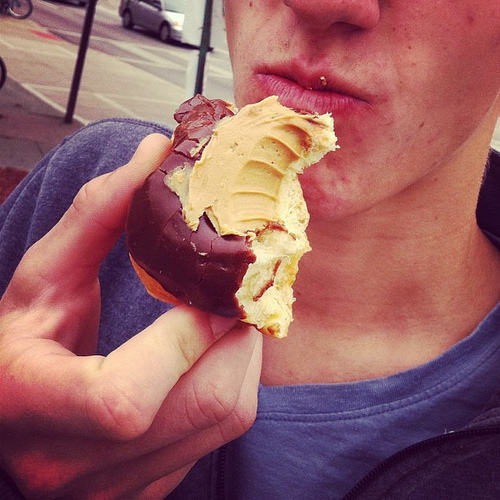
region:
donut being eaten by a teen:
[133, 93, 340, 336]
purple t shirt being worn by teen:
[6, 122, 498, 499]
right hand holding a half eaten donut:
[2, 135, 263, 495]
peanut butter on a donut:
[190, 98, 336, 236]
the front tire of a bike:
[3, 0, 39, 22]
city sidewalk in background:
[0, 11, 190, 121]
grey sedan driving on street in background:
[115, 0, 200, 47]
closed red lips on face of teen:
[247, 57, 379, 119]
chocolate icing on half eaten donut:
[127, 95, 254, 320]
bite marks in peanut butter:
[239, 125, 313, 226]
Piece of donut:
[113, 76, 344, 348]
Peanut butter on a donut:
[186, 93, 322, 237]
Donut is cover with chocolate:
[113, 89, 258, 317]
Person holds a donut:
[0, 0, 496, 487]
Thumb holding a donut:
[21, 124, 178, 269]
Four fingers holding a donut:
[45, 296, 275, 497]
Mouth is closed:
[248, 51, 368, 116]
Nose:
[285, 0, 390, 36]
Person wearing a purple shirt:
[0, 4, 498, 496]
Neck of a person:
[334, 150, 495, 294]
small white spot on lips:
[308, 59, 348, 95]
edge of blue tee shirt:
[285, 378, 346, 393]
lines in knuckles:
[95, 380, 161, 443]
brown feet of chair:
[48, 68, 99, 122]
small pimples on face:
[395, 95, 450, 166]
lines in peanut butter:
[218, 134, 289, 196]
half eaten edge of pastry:
[222, 222, 328, 342]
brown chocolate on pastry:
[166, 206, 219, 283]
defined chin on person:
[373, 126, 482, 197]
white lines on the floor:
[45, 39, 144, 104]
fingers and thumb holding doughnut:
[13, 25, 450, 467]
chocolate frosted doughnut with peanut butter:
[140, 86, 342, 288]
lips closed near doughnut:
[236, 36, 386, 137]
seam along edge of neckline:
[275, 332, 486, 427]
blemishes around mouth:
[235, 27, 472, 207]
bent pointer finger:
[31, 345, 183, 447]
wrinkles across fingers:
[182, 370, 254, 445]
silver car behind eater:
[86, 5, 287, 142]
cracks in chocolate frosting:
[157, 70, 222, 195]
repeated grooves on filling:
[211, 102, 321, 248]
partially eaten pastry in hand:
[113, 81, 343, 338]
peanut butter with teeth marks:
[222, 92, 319, 237]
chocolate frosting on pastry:
[146, 213, 243, 290]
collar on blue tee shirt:
[303, 343, 444, 430]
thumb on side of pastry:
[114, 129, 173, 206]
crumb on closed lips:
[251, 63, 372, 115]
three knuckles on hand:
[86, 387, 263, 438]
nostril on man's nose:
[325, 7, 375, 40]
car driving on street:
[115, 1, 212, 51]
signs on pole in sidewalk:
[176, 9, 220, 94]